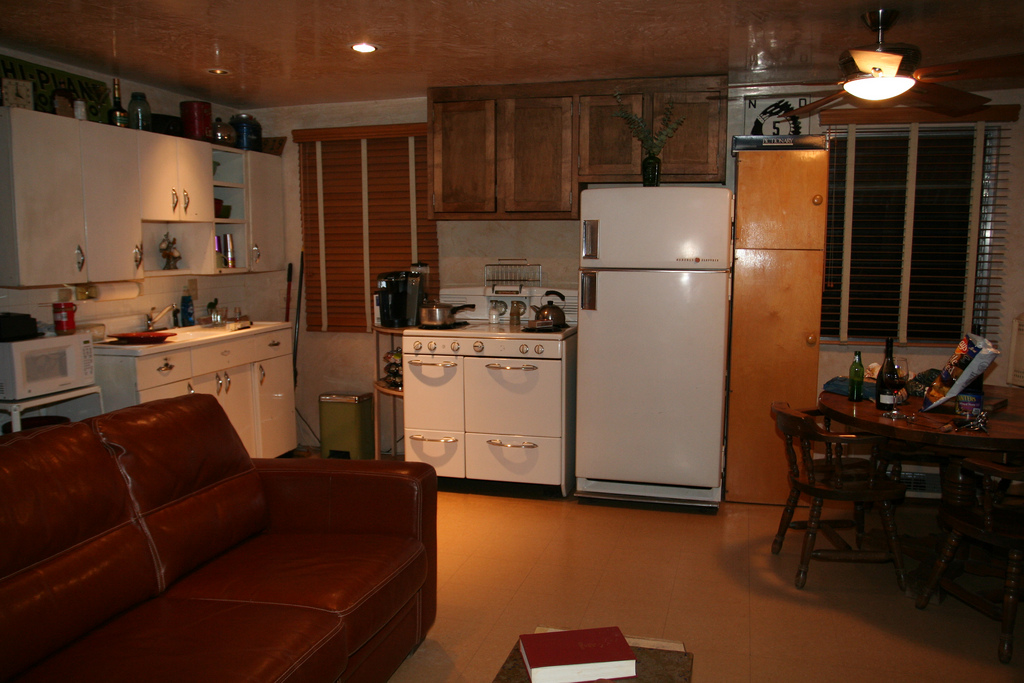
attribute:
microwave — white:
[4, 331, 99, 401]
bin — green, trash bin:
[315, 385, 370, 468]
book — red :
[517, 617, 638, 679]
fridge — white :
[572, 184, 724, 516]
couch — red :
[6, 380, 441, 679]